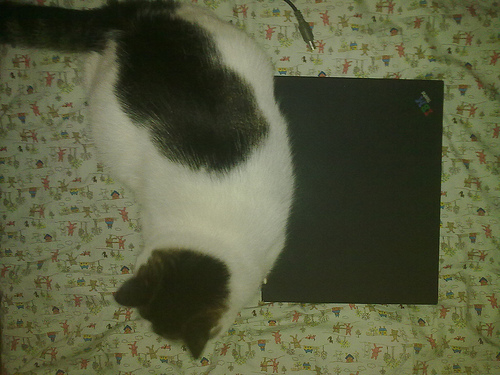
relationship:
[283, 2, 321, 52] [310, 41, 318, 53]
plug has silver tip